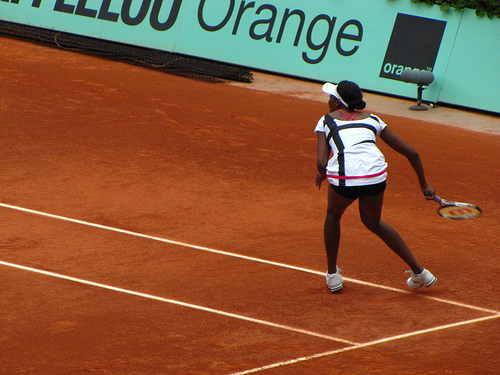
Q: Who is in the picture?
A: Black tennis player.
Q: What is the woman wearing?
A: White dress.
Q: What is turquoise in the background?
A: Advertising banner.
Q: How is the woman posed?
A: Crouched and ready to swing.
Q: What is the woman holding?
A: A racket.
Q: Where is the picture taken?
A: Tennis court.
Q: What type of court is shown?
A: Clay.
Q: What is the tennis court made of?
A: Dirt.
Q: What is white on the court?
A: Lines.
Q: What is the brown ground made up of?
A: Dirt.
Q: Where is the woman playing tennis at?
A: Tennis court.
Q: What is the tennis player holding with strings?
A: Racket.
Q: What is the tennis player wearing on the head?
A: Visor.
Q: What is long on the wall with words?
A: Banner.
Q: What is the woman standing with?
A: Legs.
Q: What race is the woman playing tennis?
A: African American.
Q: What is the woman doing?
A: Playing tennis.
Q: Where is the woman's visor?
A: On her head.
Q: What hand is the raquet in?
A: Right.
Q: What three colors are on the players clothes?
A: Black, white and pink.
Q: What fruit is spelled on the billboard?
A: Orange.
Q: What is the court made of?
A: Red clay.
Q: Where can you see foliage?
A: Above the sponsers board.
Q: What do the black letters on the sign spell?
A: Orange.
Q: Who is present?
A: A woman.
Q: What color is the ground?
A: Brown.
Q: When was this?
A: Daytime.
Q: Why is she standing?
A: To hit the ball.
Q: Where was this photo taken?
A: Tennis court.